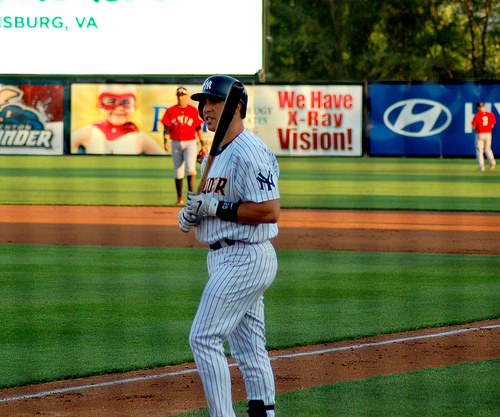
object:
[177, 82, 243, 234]
bat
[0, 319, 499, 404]
line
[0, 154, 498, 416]
baseball field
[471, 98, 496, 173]
outfielder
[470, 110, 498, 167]
uniform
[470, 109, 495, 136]
jersey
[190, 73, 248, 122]
helmet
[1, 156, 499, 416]
grass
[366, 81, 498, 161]
banner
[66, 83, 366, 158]
banner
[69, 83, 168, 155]
baby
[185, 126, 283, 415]
uniform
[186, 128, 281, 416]
blue stripes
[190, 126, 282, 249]
jersey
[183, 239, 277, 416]
pants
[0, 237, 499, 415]
infield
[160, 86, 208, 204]
man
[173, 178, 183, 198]
shin guard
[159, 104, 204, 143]
jersey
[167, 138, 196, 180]
pants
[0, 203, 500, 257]
dirt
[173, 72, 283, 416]
batter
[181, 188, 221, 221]
glove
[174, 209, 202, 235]
glove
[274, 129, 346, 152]
vision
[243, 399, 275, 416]
ankle support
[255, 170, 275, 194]
new york yankee sign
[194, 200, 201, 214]
nike logo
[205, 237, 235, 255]
belt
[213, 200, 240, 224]
sweatband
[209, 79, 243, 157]
part of bat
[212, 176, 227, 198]
letters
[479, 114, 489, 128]
3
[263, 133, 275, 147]
white